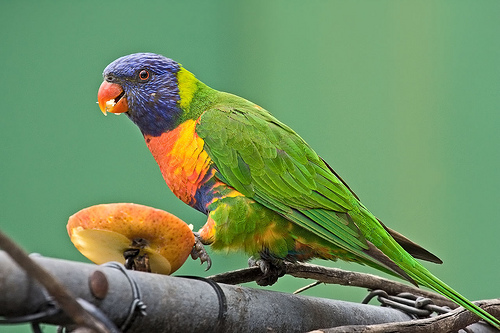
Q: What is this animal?
A: A bird.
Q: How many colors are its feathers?
A: Four.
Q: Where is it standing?
A: On a branch.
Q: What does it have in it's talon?
A: An apple.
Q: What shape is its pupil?
A: Round.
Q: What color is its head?
A: Blue.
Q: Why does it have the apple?
A: To eat.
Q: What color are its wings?
A: Green.